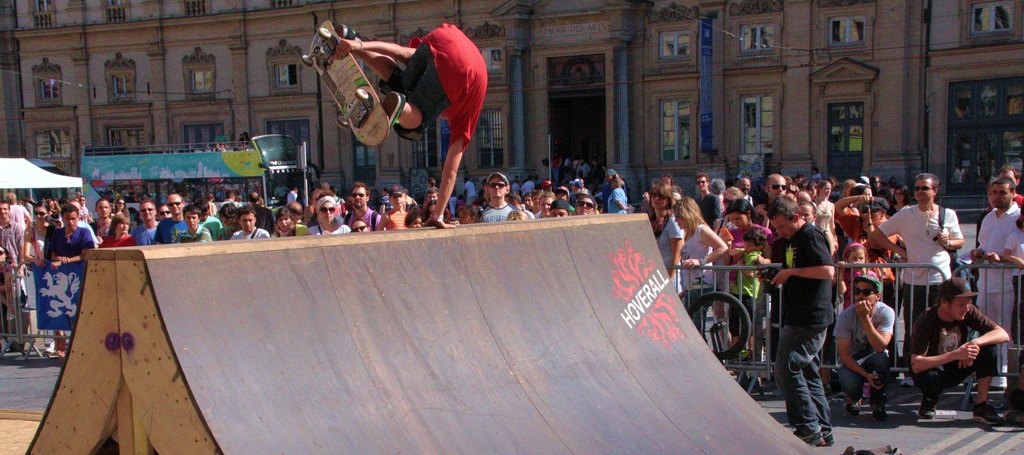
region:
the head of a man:
[757, 198, 821, 244]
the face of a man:
[754, 212, 789, 238]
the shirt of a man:
[766, 230, 842, 352]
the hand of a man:
[766, 250, 798, 293]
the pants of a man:
[713, 315, 838, 449]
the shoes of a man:
[789, 417, 835, 452]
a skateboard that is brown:
[275, 28, 389, 150]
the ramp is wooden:
[19, 204, 826, 446]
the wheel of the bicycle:
[691, 288, 746, 356]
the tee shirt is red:
[412, 13, 488, 144]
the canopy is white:
[0, 149, 80, 198]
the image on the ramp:
[607, 231, 690, 343]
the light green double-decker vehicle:
[65, 127, 307, 230]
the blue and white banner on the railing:
[23, 257, 85, 338]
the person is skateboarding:
[296, 13, 512, 242]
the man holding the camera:
[740, 188, 861, 444]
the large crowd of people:
[3, 175, 1012, 273]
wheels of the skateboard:
[329, 82, 371, 128]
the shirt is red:
[435, 20, 490, 145]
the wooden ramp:
[19, 210, 829, 452]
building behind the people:
[5, 1, 1021, 173]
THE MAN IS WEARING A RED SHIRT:
[419, 14, 490, 150]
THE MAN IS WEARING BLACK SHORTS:
[390, 26, 455, 141]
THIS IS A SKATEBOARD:
[292, 17, 387, 155]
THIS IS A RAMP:
[38, 194, 849, 450]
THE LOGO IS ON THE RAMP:
[592, 232, 692, 376]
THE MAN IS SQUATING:
[895, 267, 1019, 446]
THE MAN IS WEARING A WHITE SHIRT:
[870, 194, 966, 292]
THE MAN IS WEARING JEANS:
[762, 312, 838, 452]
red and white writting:
[588, 227, 691, 379]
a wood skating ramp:
[6, 195, 801, 453]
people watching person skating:
[3, 0, 1007, 427]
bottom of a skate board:
[293, 6, 392, 161]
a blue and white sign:
[21, 269, 79, 356]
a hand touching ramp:
[378, 200, 489, 254]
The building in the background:
[9, 15, 1021, 219]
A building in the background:
[6, 16, 1006, 228]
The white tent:
[3, 136, 93, 209]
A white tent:
[0, 141, 88, 203]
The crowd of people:
[8, 124, 989, 453]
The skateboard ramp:
[6, 195, 817, 453]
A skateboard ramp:
[16, 184, 914, 453]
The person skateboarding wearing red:
[267, 14, 543, 226]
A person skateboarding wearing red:
[275, 22, 541, 223]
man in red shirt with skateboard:
[296, 16, 489, 235]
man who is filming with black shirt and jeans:
[751, 191, 838, 452]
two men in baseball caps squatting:
[832, 273, 1009, 428]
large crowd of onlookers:
[1, 162, 1019, 400]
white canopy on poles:
[0, 156, 87, 223]